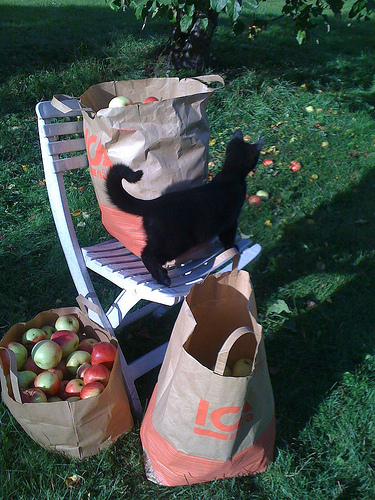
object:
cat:
[105, 129, 265, 287]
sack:
[0, 293, 133, 461]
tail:
[105, 165, 152, 217]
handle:
[76, 294, 112, 337]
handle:
[0, 344, 22, 404]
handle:
[204, 246, 240, 277]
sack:
[136, 247, 278, 487]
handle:
[212, 326, 258, 377]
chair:
[33, 92, 263, 420]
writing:
[191, 397, 256, 442]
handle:
[50, 92, 80, 117]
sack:
[50, 71, 227, 263]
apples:
[107, 96, 133, 110]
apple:
[90, 341, 112, 369]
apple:
[31, 339, 62, 368]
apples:
[234, 358, 252, 380]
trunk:
[150, 5, 215, 75]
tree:
[106, 1, 373, 81]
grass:
[3, 5, 374, 499]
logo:
[84, 129, 110, 178]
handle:
[197, 72, 228, 100]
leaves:
[276, 120, 283, 127]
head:
[224, 129, 265, 173]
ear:
[253, 137, 264, 150]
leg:
[144, 249, 167, 284]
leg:
[226, 228, 236, 252]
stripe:
[144, 417, 278, 487]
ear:
[232, 126, 244, 142]